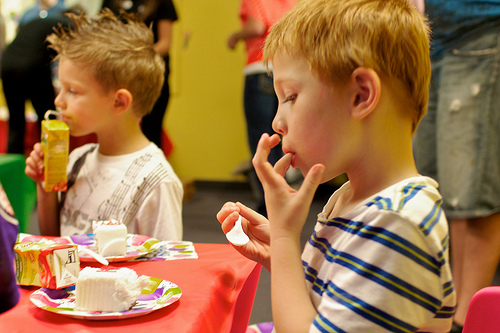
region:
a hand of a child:
[253, 132, 329, 229]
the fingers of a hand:
[250, 130, 290, 174]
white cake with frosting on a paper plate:
[56, 267, 161, 319]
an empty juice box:
[10, 235, 80, 296]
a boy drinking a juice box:
[29, 25, 164, 197]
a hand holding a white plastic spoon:
[214, 193, 268, 268]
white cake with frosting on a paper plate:
[71, 215, 158, 263]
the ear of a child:
[109, 86, 134, 116]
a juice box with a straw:
[38, 107, 70, 194]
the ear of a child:
[344, 64, 382, 122]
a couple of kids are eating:
[19, 8, 469, 331]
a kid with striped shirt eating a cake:
[217, 0, 476, 331]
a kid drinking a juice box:
[14, 3, 201, 253]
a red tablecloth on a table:
[3, 218, 282, 330]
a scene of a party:
[1, 3, 491, 331]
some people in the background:
[0, 1, 499, 243]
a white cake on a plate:
[29, 259, 183, 329]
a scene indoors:
[2, 3, 497, 319]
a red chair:
[452, 276, 499, 331]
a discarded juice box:
[5, 230, 91, 294]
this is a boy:
[217, 0, 452, 330]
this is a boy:
[41, 6, 194, 272]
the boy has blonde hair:
[255, 0, 441, 172]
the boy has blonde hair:
[26, 7, 163, 126]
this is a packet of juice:
[33, 112, 72, 196]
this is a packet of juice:
[10, 228, 91, 290]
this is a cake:
[66, 254, 146, 318]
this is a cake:
[88, 205, 156, 282]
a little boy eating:
[217, 2, 458, 327]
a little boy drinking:
[25, 10, 186, 238]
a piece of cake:
[74, 263, 133, 313]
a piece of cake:
[91, 218, 126, 255]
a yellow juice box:
[37, 117, 72, 192]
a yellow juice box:
[9, 239, 76, 288]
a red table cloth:
[4, 234, 261, 331]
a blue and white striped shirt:
[299, 175, 458, 330]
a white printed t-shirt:
[55, 138, 186, 238]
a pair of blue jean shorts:
[404, 35, 499, 215]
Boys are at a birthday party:
[4, 1, 477, 323]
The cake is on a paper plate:
[36, 254, 191, 324]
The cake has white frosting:
[44, 255, 151, 313]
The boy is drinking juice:
[21, 98, 92, 200]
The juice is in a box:
[16, 100, 86, 202]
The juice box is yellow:
[23, 91, 90, 200]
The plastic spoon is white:
[208, 181, 260, 254]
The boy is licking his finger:
[230, 121, 352, 196]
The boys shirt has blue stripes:
[232, 151, 492, 331]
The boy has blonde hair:
[253, 1, 461, 158]